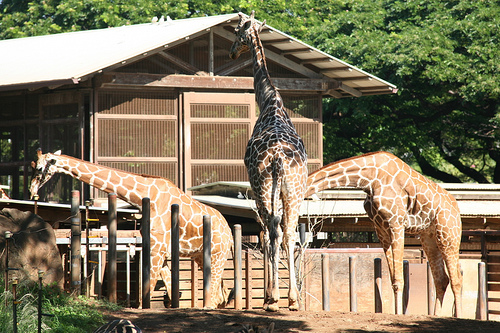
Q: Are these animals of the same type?
A: No, there are both giraffes and birds.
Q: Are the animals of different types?
A: Yes, they are giraffes and birds.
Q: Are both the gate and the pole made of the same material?
A: No, the gate is made of wood and the pole is made of metal.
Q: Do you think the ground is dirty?
A: Yes, the ground is dirty.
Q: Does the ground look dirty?
A: Yes, the ground is dirty.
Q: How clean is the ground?
A: The ground is dirty.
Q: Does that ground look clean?
A: No, the ground is dirty.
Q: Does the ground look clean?
A: No, the ground is dirty.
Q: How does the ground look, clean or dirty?
A: The ground is dirty.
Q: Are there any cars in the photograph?
A: No, there are no cars.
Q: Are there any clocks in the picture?
A: No, there are no clocks.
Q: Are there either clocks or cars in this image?
A: No, there are no clocks or cars.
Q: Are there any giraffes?
A: Yes, there is a giraffe.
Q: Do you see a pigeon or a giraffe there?
A: Yes, there is a giraffe.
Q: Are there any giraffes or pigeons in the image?
A: Yes, there is a giraffe.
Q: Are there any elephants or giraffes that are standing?
A: Yes, the giraffe is standing.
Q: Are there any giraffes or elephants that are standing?
A: Yes, the giraffe is standing.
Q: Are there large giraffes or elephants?
A: Yes, there is a large giraffe.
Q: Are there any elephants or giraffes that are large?
A: Yes, the giraffe is large.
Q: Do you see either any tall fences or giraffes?
A: Yes, there is a tall giraffe.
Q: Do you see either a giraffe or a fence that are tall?
A: Yes, the giraffe is tall.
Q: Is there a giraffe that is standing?
A: Yes, there is a giraffe that is standing.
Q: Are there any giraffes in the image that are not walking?
A: Yes, there is a giraffe that is standing.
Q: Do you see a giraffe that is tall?
A: Yes, there is a tall giraffe.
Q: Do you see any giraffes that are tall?
A: Yes, there is a giraffe that is tall.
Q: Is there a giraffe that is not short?
A: Yes, there is a tall giraffe.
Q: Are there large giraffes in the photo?
A: Yes, there is a large giraffe.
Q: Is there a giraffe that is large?
A: Yes, there is a giraffe that is large.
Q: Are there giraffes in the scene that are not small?
A: Yes, there is a large giraffe.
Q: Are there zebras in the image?
A: No, there are no zebras.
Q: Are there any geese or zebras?
A: No, there are no zebras or geese.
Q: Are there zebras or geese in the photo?
A: No, there are no zebras or geese.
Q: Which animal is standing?
A: The animal is a giraffe.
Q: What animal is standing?
A: The animal is a giraffe.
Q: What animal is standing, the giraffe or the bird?
A: The giraffe is standing.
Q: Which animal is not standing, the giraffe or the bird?
A: The bird is not standing.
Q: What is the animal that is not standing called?
A: The animal is a bird.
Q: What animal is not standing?
A: The animal is a bird.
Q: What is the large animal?
A: The animal is a giraffe.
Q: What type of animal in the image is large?
A: The animal is a giraffe.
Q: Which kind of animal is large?
A: The animal is a giraffe.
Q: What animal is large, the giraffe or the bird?
A: The giraffe is large.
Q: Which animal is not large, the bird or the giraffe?
A: The bird is not large.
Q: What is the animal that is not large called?
A: The animal is a bird.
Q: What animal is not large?
A: The animal is a bird.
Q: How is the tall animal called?
A: The animal is a giraffe.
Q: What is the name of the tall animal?
A: The animal is a giraffe.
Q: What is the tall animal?
A: The animal is a giraffe.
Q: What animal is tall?
A: The animal is a giraffe.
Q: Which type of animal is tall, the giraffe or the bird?
A: The giraffe is tall.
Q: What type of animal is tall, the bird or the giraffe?
A: The giraffe is tall.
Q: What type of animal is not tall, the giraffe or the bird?
A: The bird is not tall.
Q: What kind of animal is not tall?
A: The animal is a bird.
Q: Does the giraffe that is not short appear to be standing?
A: Yes, the giraffe is standing.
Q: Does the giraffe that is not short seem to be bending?
A: No, the giraffe is standing.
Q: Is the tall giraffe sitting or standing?
A: The giraffe is standing.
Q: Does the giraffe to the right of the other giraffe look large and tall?
A: Yes, the giraffe is large and tall.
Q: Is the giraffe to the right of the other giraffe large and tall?
A: Yes, the giraffe is large and tall.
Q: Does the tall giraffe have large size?
A: Yes, the giraffe is large.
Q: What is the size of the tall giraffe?
A: The giraffe is large.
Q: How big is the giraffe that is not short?
A: The giraffe is large.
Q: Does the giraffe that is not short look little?
A: No, the giraffe is large.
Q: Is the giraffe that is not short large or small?
A: The giraffe is large.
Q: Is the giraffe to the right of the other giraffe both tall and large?
A: Yes, the giraffe is tall and large.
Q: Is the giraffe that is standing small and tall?
A: No, the giraffe is tall but large.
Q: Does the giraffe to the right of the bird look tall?
A: Yes, the giraffe is tall.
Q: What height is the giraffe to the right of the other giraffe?
A: The giraffe is tall.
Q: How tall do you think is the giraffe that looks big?
A: The giraffe is tall.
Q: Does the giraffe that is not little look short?
A: No, the giraffe is tall.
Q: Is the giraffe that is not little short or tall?
A: The giraffe is tall.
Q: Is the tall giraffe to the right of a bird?
A: Yes, the giraffe is to the right of a bird.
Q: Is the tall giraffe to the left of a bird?
A: No, the giraffe is to the right of a bird.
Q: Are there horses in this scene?
A: No, there are no horses.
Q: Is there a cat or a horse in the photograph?
A: No, there are no horses or cats.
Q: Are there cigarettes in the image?
A: No, there are no cigarettes.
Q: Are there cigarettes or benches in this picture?
A: No, there are no cigarettes or benches.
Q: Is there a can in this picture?
A: No, there are no cans.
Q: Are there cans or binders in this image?
A: No, there are no cans or binders.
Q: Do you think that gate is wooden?
A: Yes, the gate is wooden.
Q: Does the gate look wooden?
A: Yes, the gate is wooden.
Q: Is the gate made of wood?
A: Yes, the gate is made of wood.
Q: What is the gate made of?
A: The gate is made of wood.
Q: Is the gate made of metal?
A: No, the gate is made of wood.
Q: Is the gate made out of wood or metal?
A: The gate is made of wood.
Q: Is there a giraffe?
A: Yes, there is a giraffe.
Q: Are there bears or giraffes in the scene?
A: Yes, there is a giraffe.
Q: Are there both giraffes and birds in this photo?
A: Yes, there are both a giraffe and a bird.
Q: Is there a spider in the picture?
A: No, there are no spiders.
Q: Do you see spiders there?
A: No, there are no spiders.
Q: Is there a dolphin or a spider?
A: No, there are no spiders or dolphins.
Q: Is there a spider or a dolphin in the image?
A: No, there are no spiders or dolphins.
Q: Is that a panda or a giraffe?
A: That is a giraffe.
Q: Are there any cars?
A: No, there are no cars.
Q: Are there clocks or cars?
A: No, there are no cars or clocks.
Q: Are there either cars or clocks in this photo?
A: No, there are no cars or clocks.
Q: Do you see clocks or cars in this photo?
A: No, there are no cars or clocks.